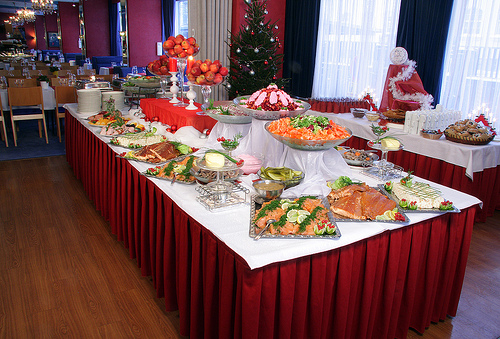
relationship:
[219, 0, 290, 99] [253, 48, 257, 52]
christmas tree has ornaments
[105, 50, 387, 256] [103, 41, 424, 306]
food on table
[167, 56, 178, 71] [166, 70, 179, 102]
candle on candlestick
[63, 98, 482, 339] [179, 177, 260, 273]
tablecloth around table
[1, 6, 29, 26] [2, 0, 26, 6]
lights on ceiling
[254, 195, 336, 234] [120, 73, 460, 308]
food on table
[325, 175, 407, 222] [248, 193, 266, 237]
food on tray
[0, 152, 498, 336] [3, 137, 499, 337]
wooden floor on floor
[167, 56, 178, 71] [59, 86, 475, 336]
candle on table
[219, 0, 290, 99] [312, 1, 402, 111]
christmas tree by window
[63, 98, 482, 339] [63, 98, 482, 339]
tablecloth under tablecloth